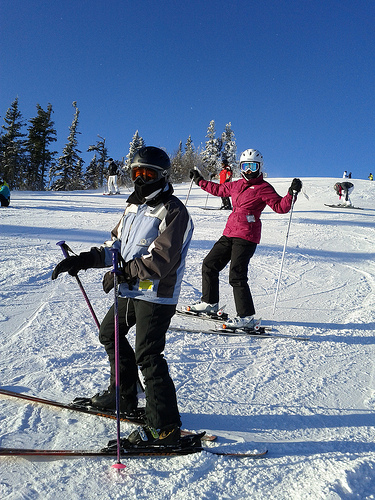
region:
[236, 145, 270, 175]
woman has silver helmet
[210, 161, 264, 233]
woman has pink coat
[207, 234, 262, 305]
woman has black pants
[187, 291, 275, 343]
woman has white boots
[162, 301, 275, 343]
woman has black skis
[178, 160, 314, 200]
woman has black gloves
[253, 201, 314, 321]
woman holds white ski poles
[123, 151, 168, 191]
man has black helmet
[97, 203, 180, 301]
blue and black coat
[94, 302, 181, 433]
man has black pants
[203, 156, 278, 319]
A person snow sketing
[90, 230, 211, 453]
A person snow sketing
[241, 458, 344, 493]
A snow filled ground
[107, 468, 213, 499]
A snow filled ground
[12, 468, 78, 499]
A snow filled ground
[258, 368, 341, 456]
A snow filled ground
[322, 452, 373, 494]
A snow filled ground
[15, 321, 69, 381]
A snow filled ground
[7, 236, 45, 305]
A snow filled ground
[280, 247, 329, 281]
A snow filled ground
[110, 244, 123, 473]
purple, pink and blue ski pole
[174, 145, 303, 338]
person in red wearing snow skis, helmet and goggles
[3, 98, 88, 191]
tall green pine trees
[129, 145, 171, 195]
ski helmet with goggles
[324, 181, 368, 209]
person with skis and red scarf bending over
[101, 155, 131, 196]
person skiing in dark coat and white pants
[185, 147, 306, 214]
skier with arms outstretched holding ski poles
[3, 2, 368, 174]
blue, cloudless sky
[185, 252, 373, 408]
ski tracks in the white snow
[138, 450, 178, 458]
orange writing on edge of skis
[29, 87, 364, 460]
People out enjoying the ski slopes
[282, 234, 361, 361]
The ground is snow covered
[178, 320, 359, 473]
The snow has a lot of tracks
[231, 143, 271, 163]
The woman is wearing a helmet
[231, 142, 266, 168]
The woman's helmet is white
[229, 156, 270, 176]
The woman is wearing goggles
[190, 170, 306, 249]
The woman is wearing a jacket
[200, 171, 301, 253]
The woman's jacket is rose colored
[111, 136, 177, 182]
The man is wearing a helmet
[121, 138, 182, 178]
The man's helmet is black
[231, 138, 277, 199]
the helmet is white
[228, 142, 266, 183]
the helmet is white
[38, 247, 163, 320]
the gloves are black